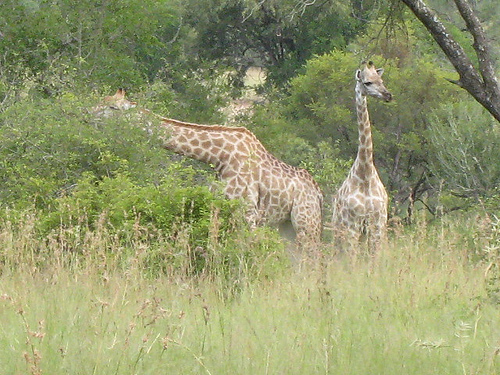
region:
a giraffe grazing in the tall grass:
[86, 87, 325, 304]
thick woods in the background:
[1, 0, 98, 267]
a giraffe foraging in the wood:
[332, 60, 394, 269]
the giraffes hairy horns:
[359, 58, 376, 70]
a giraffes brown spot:
[201, 138, 212, 150]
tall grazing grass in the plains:
[1, 248, 499, 374]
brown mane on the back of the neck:
[158, 115, 251, 136]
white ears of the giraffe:
[377, 65, 384, 77]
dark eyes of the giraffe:
[363, 79, 373, 89]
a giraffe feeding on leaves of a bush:
[1, 87, 323, 299]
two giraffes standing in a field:
[90, 43, 408, 278]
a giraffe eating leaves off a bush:
[78, 83, 151, 136]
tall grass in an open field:
[32, 225, 487, 358]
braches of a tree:
[407, 3, 497, 107]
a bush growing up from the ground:
[62, 173, 244, 262]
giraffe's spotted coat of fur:
[245, 163, 289, 198]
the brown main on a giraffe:
[150, 108, 243, 133]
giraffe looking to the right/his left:
[349, 59, 397, 104]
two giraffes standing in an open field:
[81, 35, 424, 267]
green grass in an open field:
[345, 327, 406, 362]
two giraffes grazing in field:
[84, 63, 394, 266]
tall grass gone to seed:
[0, 192, 497, 371]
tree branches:
[395, 1, 498, 118]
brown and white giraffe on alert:
[329, 59, 394, 243]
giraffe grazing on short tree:
[91, 88, 321, 248]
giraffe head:
[353, 59, 390, 103]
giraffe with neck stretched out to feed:
[84, 87, 321, 259]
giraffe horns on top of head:
[358, 60, 372, 68]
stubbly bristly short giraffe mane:
[133, 104, 253, 134]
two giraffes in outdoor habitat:
[8, 0, 498, 371]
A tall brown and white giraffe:
[328, 61, 426, 296]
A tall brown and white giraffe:
[84, 81, 332, 272]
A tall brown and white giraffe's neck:
[330, 87, 380, 169]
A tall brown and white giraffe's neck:
[132, 103, 216, 161]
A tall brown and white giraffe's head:
[355, 47, 392, 111]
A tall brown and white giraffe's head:
[81, 83, 136, 130]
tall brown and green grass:
[30, 210, 140, 364]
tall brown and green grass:
[160, 247, 258, 361]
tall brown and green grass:
[272, 268, 382, 372]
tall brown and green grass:
[421, 210, 489, 360]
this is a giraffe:
[328, 57, 418, 270]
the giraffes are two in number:
[111, 72, 429, 242]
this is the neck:
[346, 97, 388, 169]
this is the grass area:
[335, 280, 477, 330]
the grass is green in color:
[283, 311, 348, 348]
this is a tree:
[27, 105, 94, 213]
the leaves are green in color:
[44, 110, 84, 156]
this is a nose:
[351, 62, 361, 87]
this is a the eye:
[363, 78, 379, 88]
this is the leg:
[295, 212, 336, 283]